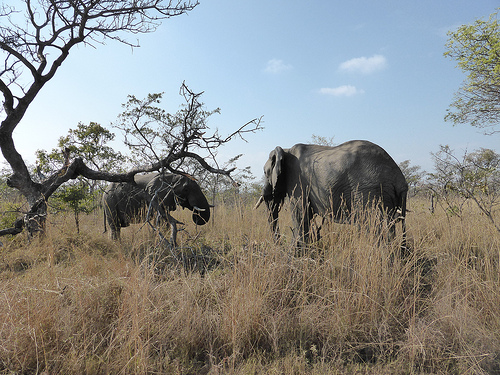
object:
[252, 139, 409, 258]
elephant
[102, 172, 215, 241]
elephant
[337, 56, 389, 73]
clouds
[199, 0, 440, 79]
sky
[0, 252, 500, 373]
grass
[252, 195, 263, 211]
tusk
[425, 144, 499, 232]
trees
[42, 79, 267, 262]
branches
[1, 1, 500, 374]
field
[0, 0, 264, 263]
tree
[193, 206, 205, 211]
tusks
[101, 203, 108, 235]
tail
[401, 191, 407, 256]
tail